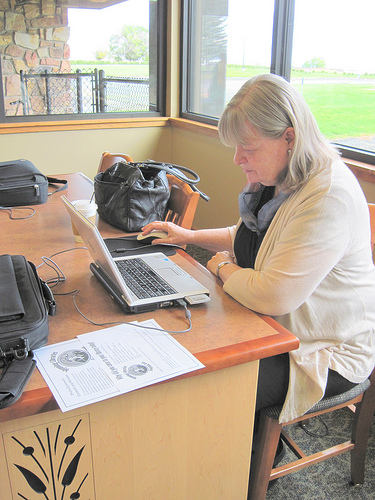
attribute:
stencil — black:
[10, 418, 88, 499]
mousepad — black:
[101, 230, 177, 255]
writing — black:
[87, 341, 124, 381]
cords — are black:
[37, 243, 191, 333]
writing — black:
[99, 328, 144, 365]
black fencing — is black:
[18, 68, 153, 114]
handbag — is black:
[84, 149, 212, 234]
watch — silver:
[216, 260, 234, 278]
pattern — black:
[2, 418, 96, 499]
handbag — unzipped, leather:
[97, 162, 188, 232]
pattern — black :
[5, 416, 110, 499]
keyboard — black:
[52, 188, 227, 327]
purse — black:
[93, 161, 172, 231]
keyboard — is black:
[117, 248, 198, 310]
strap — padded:
[0, 355, 41, 408]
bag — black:
[0, 249, 61, 354]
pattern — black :
[3, 411, 97, 498]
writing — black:
[61, 364, 112, 398]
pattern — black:
[3, 426, 94, 498]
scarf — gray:
[233, 182, 288, 270]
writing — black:
[49, 345, 89, 371]